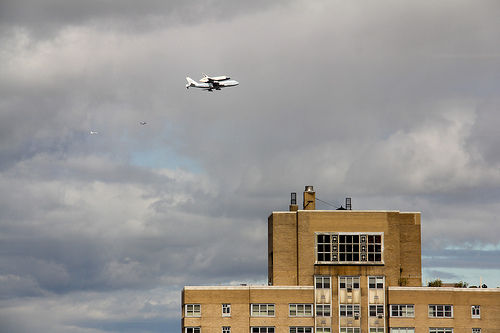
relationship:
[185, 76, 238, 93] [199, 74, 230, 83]
plane carrying shuttle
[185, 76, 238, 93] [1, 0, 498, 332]
plane in sky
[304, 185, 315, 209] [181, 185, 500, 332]
chimney on building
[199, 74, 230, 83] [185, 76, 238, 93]
shuttle on plane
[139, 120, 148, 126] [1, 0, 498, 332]
jet in sky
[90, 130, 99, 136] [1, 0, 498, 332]
jet in sky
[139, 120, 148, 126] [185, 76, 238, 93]
jet behind plane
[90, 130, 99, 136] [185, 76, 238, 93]
jet behind plane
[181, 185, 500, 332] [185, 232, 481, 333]
building has windows